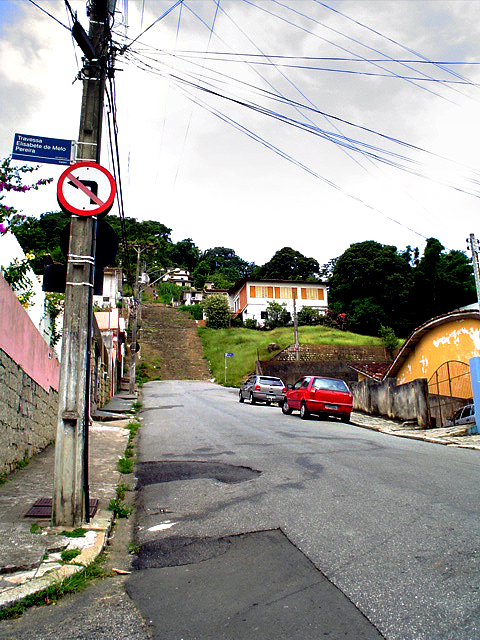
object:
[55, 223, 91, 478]
sign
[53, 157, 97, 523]
pole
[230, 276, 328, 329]
house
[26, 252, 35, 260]
flower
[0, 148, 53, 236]
flower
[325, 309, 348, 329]
flower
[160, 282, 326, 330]
bush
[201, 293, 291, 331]
bush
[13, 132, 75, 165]
sign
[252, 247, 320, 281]
tree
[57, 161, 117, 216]
sign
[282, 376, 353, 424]
car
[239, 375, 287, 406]
car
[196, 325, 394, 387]
grass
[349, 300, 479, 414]
building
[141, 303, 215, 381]
dirt